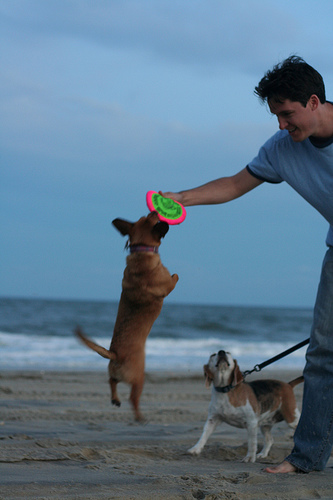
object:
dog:
[72, 209, 179, 420]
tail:
[72, 321, 118, 360]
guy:
[157, 55, 332, 480]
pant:
[282, 247, 333, 473]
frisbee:
[146, 189, 187, 225]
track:
[106, 425, 191, 440]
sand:
[0, 373, 333, 500]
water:
[0, 285, 315, 373]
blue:
[146, 246, 150, 252]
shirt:
[245, 128, 333, 247]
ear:
[309, 94, 319, 112]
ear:
[111, 215, 134, 238]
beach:
[0, 364, 331, 499]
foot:
[262, 459, 297, 474]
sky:
[0, 0, 333, 305]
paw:
[111, 398, 121, 408]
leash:
[242, 336, 310, 379]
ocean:
[0, 295, 315, 343]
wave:
[0, 329, 308, 378]